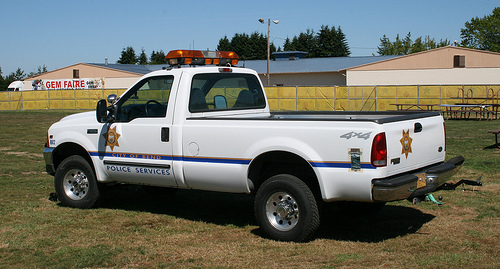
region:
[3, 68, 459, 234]
this is a pick up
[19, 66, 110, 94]
this is a sign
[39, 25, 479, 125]
this is a house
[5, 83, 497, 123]
the fence is yellow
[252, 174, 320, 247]
a wheel of a pick up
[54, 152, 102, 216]
a wheel of a pick up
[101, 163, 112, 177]
a letter is written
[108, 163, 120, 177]
a letter is written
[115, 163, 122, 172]
a letter is written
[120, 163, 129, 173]
a letter is written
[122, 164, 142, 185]
a letter is written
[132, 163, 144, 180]
a letter is written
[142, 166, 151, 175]
a letter is written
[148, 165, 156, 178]
a letter is written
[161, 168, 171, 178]
a letter is written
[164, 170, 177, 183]
a letter is written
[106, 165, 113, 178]
a letter is written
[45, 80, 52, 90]
a letter is written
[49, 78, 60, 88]
a letter is written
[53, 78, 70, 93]
a letter is written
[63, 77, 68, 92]
a letter is written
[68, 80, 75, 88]
a letter is written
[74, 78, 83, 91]
a letter is written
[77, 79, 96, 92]
a letter is written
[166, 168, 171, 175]
a letter is written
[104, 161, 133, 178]
a word written in white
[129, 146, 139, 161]
a word written in white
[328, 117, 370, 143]
a word written in white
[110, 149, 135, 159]
a word written in white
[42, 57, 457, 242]
this is a truck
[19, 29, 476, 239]
the truck is white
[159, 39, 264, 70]
light bar on truck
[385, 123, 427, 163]
star on the truck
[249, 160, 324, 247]
back tires on truck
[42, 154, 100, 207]
front tire on truck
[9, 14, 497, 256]
truck parked on grass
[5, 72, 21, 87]
a tree in a distance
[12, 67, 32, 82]
a tree in a distance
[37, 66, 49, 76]
a tree in a distance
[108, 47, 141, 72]
a tree in a distance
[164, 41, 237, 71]
yellow lights on the truck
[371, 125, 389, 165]
red brake light on the truck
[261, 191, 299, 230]
silver rim on the truck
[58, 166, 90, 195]
silver rim on the truck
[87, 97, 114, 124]
black mirror on the truck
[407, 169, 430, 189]
license plate on the truck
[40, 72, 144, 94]
banner on the building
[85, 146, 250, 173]
blue stripe on the truck